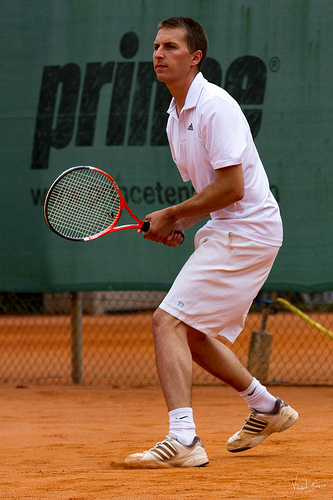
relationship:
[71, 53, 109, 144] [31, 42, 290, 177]
letter on a sign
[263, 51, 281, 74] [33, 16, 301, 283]
letter on a sign